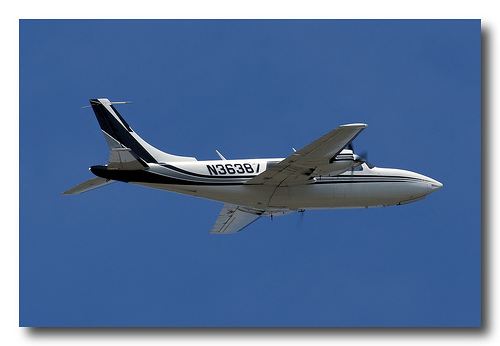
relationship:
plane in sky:
[62, 95, 447, 239] [254, 37, 458, 126]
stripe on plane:
[148, 180, 411, 187] [62, 95, 447, 239]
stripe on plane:
[162, 156, 419, 178] [62, 95, 447, 239]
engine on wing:
[280, 185, 313, 222] [205, 196, 311, 237]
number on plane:
[202, 156, 263, 180] [45, 57, 457, 262]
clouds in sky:
[22, 19, 479, 327] [21, 22, 483, 325]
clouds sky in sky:
[323, 234, 469, 321] [21, 22, 483, 325]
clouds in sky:
[101, 257, 238, 334] [323, 62, 425, 106]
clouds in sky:
[393, 85, 457, 145] [21, 22, 483, 325]